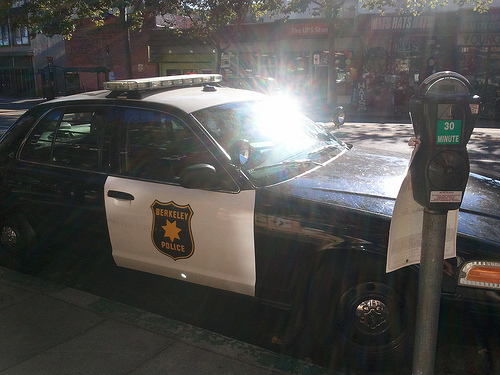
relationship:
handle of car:
[103, 187, 138, 199] [9, 75, 498, 370]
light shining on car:
[258, 97, 330, 159] [9, 75, 498, 370]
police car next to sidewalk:
[10, 58, 499, 373] [1, 255, 331, 373]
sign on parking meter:
[433, 119, 462, 146] [398, 69, 484, 364]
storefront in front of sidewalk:
[449, 13, 499, 103] [13, 288, 317, 373]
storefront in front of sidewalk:
[354, 11, 434, 121] [13, 288, 317, 373]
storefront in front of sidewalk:
[260, 9, 331, 113] [13, 288, 317, 373]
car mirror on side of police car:
[329, 100, 348, 132] [1, 71, 496, 343]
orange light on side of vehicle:
[454, 258, 498, 302] [9, 74, 498, 355]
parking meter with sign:
[407, 69, 481, 374] [380, 142, 465, 274]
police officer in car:
[211, 111, 273, 167] [15, 46, 498, 358]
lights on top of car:
[97, 68, 229, 93] [5, 87, 497, 307]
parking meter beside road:
[398, 69, 484, 364] [0, 87, 486, 171]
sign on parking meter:
[433, 115, 468, 146] [407, 69, 481, 374]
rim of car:
[349, 292, 399, 342] [24, 62, 497, 320]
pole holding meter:
[410, 212, 447, 374] [409, 72, 480, 374]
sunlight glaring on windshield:
[244, 86, 326, 152] [192, 92, 350, 189]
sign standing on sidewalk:
[353, 81, 368, 117] [307, 100, 489, 127]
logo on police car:
[149, 194, 204, 268] [1, 71, 496, 343]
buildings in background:
[28, 27, 487, 82] [1, 3, 499, 111]